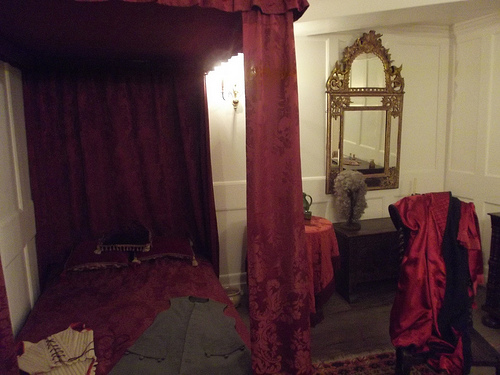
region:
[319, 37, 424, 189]
mirror on the wall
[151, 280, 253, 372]
clothing on the bed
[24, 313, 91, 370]
clothing on the bed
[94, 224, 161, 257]
pillow on the bed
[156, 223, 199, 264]
pillow on the bed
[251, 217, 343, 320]
table on the side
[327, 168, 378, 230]
wig on the side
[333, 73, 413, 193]
mirror outlined in gold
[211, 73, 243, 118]
sconce on the wall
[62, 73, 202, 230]
drapery behind the bed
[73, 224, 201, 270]
pillow on bed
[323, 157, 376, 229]
wig on a dresser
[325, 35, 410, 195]
mirror on the wall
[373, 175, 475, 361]
bath robe on a chair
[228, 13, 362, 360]
curtain over a bed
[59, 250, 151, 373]
bed sheet on a bed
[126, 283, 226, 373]
dress on the bed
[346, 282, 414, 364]
carpet on the floor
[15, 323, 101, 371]
shirt on the bed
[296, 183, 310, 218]
tea pot on the table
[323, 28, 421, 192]
golf mirror on the wall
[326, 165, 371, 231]
stand with a wig on the dresser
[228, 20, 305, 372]
drapes on the bed post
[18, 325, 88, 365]
corset on the bed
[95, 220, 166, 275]
pillows with fringe on the bed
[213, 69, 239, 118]
light fixture on the wall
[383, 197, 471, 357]
clothes on the chair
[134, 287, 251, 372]
grey dress on the bed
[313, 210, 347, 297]
fabric covering the table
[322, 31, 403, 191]
a gold filigreed frame on a mirror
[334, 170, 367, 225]
a wig on a wig stand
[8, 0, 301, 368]
heavey red drapes surround a bed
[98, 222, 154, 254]
dark burgundy velvet pillow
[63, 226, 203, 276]
red pillow shams with gold cording and tassels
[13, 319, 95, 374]
a off white laced corsette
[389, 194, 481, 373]
red clothing with black lace trim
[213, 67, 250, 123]
electric wall sconce in gold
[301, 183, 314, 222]
pitcher and bowl on a table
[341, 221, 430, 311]
a dark wood chest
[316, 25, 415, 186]
mirror on the wall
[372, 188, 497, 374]
robe draped over chair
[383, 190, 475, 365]
chair with robe on it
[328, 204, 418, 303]
desk with drawers on it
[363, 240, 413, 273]
drawers under the desk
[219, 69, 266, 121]
light on the wall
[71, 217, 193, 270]
pillows on the bed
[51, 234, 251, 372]
bed in the room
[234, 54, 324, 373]
curtains draped in front of bed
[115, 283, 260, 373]
outfit placed on bed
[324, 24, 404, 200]
mirror on the wall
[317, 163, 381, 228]
gray wig on the dresser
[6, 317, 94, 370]
vest on the bed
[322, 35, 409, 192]
a gold mirror hanging on a wall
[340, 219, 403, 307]
a square wood table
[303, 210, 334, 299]
a round table covered with a red cloth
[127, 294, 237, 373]
a dress laying on a bed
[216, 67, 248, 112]
a light fixture attached to a wall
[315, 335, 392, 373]
a rug on the floor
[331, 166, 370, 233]
a wig on a stand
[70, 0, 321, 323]
a canopy over a bed